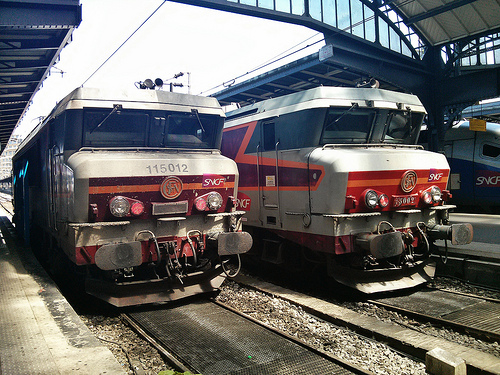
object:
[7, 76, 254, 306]
train engine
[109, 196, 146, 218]
headlight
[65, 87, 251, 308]
train front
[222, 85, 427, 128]
roof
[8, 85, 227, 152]
roof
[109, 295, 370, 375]
track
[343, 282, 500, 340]
track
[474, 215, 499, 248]
ground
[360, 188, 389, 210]
headlight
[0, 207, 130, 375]
sidewalk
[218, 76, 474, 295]
train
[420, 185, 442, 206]
headlight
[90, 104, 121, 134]
wiper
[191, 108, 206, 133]
wiper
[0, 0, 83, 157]
metal overhang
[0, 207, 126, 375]
platform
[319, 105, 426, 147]
windshield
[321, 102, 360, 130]
wipers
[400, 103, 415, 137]
wipers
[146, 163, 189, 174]
115012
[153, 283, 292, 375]
metal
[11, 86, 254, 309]
train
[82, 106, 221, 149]
windshield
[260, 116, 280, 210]
door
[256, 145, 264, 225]
handle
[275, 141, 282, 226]
handle